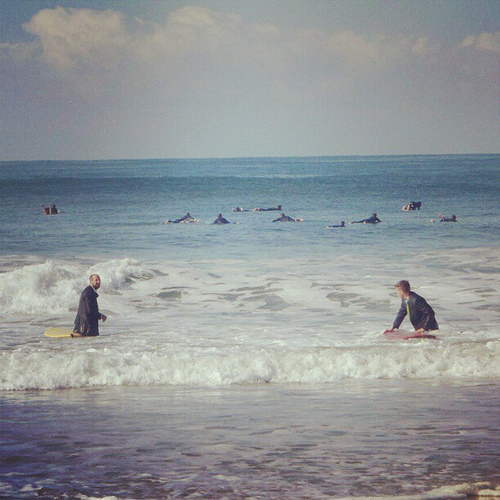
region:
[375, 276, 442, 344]
a person in suit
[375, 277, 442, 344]
a person wearing suit in the water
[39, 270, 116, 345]
a person wearing suit in the water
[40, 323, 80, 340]
a yellow surfboard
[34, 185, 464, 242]
people in the water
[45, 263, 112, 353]
man on left with yellow board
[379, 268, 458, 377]
man on right with red board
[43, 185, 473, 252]
people on boards beyond waves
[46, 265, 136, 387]
surfer with yellow board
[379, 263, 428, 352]
surfer with red board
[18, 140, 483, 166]
horizon line between sky and ocean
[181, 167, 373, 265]
group of surfers in back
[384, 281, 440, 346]
A man in the water with a surfboard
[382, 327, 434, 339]
A red surfboard in the water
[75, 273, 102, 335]
A man in a coat in the water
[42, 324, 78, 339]
A yellow surfboard in the water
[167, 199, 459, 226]
A lot of people floating in the ocean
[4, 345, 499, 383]
Frothy water rolling into the shore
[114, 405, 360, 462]
Water sliding onto a beach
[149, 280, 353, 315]
White foamy water in the ocean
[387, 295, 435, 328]
A jacket on a man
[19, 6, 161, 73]
A fat white cloud in the sky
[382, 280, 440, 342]
surfer in dark ocean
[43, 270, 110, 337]
surfer in dark ocean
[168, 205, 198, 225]
surfer in dark ocean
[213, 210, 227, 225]
surfer in dark ocean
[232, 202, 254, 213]
surfer in dark ocean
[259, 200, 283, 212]
surfer in dark ocean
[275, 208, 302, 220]
surfer in dark ocean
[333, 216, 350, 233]
surfer in dark ocean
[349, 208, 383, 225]
surfer in dark ocean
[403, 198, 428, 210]
surfer in dark ocean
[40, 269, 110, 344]
person wearing suit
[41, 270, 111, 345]
person wearing suit in water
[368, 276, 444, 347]
person wearing suit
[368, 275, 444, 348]
person wearing suit in water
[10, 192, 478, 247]
surfers in the water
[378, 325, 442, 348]
red surfboard in the water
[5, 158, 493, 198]
body of water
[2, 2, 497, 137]
clouds in the sky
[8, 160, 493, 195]
blue body of water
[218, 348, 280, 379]
the water is white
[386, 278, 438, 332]
peson in the water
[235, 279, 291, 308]
bubbles in the water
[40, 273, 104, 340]
Man in a suit with a yellow surfboard.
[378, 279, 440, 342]
Man in a suit with a red surfboard.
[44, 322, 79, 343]
Yellow surfboard being held by a man.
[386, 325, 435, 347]
Red surfboard being held by a man.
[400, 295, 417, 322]
Yellow tie on the man with a red board.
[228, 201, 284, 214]
Two men lying down the farthest out.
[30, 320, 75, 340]
Yellow surfboard floating in the water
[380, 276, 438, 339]
Man holding a surfboard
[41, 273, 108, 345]
Man in a jacket holding yellow surf board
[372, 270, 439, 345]
Man wearing a suit in the ocean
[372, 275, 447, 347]
Man holding a red surf board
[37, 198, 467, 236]
Group of men in the ocean with surfboards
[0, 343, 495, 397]
A wave crashing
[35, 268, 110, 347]
A man standing in the ocean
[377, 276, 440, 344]
Man wearing a yellow tie in the ocean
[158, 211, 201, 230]
Person swimming in the ocean